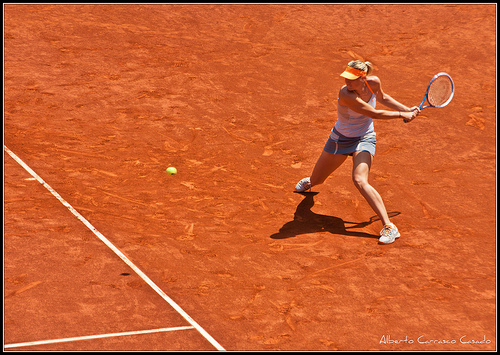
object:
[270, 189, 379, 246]
shadow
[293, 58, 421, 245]
player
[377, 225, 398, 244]
left shoe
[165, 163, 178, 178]
ball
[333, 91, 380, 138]
shirt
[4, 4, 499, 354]
tennis court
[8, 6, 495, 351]
turf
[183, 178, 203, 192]
footprint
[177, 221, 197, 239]
footprint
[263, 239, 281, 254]
footprint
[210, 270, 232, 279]
footprint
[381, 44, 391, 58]
footprint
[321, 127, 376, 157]
shorts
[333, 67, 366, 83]
visor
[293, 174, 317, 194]
shoe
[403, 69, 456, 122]
racket